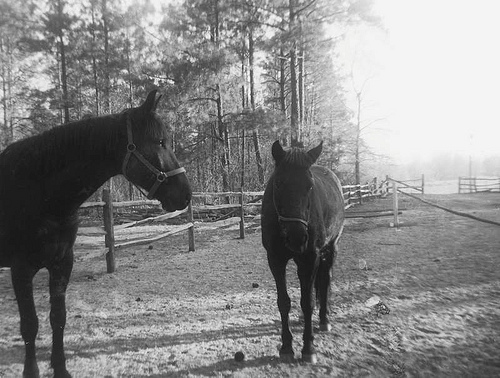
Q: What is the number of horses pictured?
A: 2.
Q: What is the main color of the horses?
A: Black.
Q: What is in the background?
A: Trees.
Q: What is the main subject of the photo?
A: 2 horses.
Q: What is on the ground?
A: Dirt.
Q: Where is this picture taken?
A: In a field.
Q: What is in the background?
A: Trees.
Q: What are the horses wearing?
A: Halters.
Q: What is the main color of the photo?
A: Black and white.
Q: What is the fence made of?
A: Wood.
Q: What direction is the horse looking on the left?
A: To the right.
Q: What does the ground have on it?
A: Dirt.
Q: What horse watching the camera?
A: Horse on right.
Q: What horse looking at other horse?
A: Horse on left.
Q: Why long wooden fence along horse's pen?
A: Keep horses in.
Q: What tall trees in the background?
A: Pine trees.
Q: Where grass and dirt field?
A: Under horse's hoof.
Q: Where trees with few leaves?
A: Back ground.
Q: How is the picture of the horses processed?
A: Black and white.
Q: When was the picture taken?
A: Daytime.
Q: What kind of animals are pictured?
A: Horses.